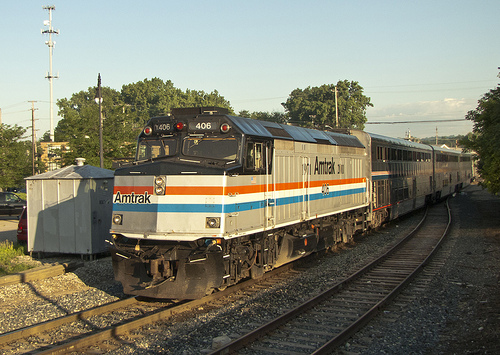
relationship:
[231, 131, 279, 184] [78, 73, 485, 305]
paint on train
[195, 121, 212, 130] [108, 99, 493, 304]
number on train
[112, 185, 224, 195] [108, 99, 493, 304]
orange stripe on a train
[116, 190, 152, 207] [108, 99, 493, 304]
black letters on train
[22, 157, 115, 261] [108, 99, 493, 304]
building by train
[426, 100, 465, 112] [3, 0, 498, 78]
clouds in sky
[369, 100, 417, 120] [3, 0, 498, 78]
clouds in sky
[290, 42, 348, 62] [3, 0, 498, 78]
clouds in sky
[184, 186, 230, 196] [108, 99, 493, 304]
paint on a train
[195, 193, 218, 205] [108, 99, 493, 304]
paint on a train